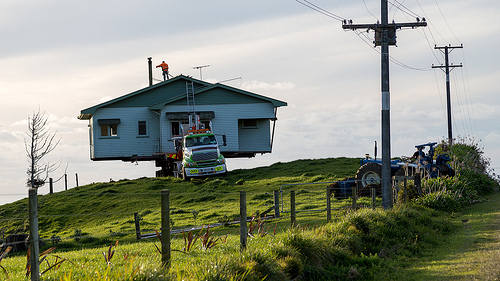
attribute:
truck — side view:
[158, 119, 245, 180]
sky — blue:
[73, 18, 130, 66]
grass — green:
[1, 177, 321, 241]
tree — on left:
[17, 110, 47, 191]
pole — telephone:
[343, 1, 425, 210]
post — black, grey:
[156, 186, 182, 256]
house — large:
[75, 56, 289, 157]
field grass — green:
[1, 157, 498, 279]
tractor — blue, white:
[334, 133, 457, 193]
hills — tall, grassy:
[275, 136, 408, 278]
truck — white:
[177, 117, 230, 182]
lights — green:
[184, 160, 202, 174]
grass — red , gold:
[170, 221, 232, 256]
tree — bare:
[18, 108, 55, 194]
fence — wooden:
[11, 167, 396, 279]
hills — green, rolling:
[18, 154, 419, 236]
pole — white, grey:
[321, 11, 486, 243]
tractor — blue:
[328, 138, 449, 203]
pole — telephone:
[434, 42, 461, 145]